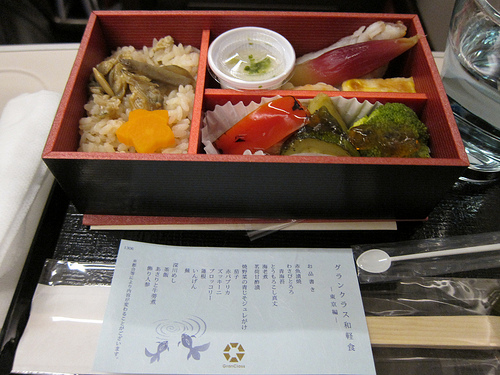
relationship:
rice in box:
[74, 36, 201, 153] [42, 10, 471, 220]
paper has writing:
[91, 239, 377, 373] [114, 246, 357, 358]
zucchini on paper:
[281, 128, 360, 159] [200, 95, 383, 157]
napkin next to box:
[1, 91, 49, 281] [42, 10, 471, 220]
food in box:
[75, 19, 433, 159] [42, 10, 471, 220]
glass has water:
[441, 0, 500, 187] [441, 10, 499, 173]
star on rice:
[116, 108, 177, 154] [74, 36, 201, 153]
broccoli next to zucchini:
[348, 101, 432, 158] [281, 126, 362, 158]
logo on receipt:
[223, 342, 245, 361] [93, 238, 376, 373]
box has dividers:
[42, 10, 471, 220] [188, 29, 428, 154]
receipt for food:
[93, 238, 376, 373] [75, 19, 433, 159]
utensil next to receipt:
[356, 242, 499, 274] [93, 238, 376, 373]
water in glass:
[441, 10, 499, 173] [441, 0, 500, 187]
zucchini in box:
[281, 128, 360, 159] [42, 10, 471, 220]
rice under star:
[74, 36, 201, 153] [116, 108, 177, 154]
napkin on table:
[1, 91, 49, 281] [0, 41, 446, 331]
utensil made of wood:
[365, 315, 499, 349] [364, 314, 499, 352]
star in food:
[116, 108, 177, 154] [75, 19, 433, 159]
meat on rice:
[89, 53, 197, 110] [74, 36, 201, 153]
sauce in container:
[225, 45, 280, 79] [207, 26, 297, 89]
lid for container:
[207, 26, 297, 94] [207, 26, 297, 89]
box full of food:
[42, 10, 471, 220] [75, 19, 433, 159]